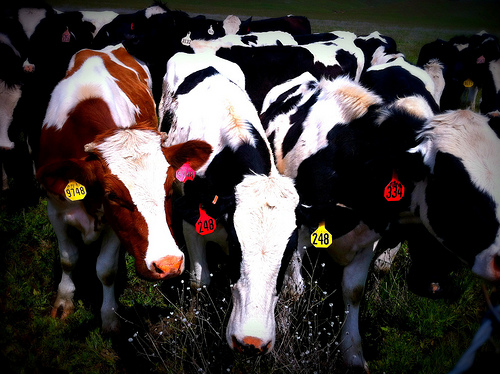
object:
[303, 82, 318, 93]
spot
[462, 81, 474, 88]
tag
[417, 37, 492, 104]
cow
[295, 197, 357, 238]
ear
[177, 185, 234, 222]
ear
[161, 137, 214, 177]
ear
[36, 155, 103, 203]
ear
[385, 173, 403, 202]
red tag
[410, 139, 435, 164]
ear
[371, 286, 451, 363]
grass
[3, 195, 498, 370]
grass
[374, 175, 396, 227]
ground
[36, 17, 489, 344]
cows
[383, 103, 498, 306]
head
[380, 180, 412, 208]
tag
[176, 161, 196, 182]
tag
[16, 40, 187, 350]
cow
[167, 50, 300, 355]
cow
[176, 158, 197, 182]
redtag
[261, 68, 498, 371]
cow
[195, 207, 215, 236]
ear tag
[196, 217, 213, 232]
248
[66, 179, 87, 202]
ear tag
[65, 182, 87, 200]
number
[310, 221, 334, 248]
ear tag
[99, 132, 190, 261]
white stripe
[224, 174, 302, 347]
white stripe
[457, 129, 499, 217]
white stripe